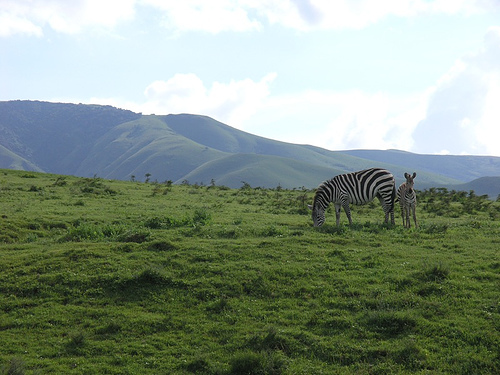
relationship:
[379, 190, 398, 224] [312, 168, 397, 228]
leg of zebra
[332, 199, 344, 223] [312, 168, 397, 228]
leg of zebra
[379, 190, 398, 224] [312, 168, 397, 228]
leg of a zebra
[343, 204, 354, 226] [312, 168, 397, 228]
leg of a zebra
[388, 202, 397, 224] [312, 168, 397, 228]
leg of a zebra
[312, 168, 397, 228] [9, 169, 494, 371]
zebra on a field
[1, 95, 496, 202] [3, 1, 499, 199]
mountain in background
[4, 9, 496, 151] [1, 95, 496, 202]
clouds touching mountains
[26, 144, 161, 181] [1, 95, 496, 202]
valley in mountains